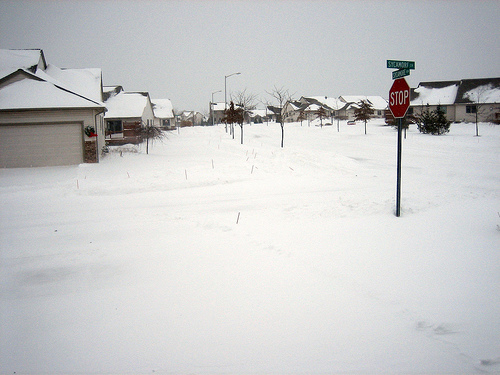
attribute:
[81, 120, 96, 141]
wreath — green, red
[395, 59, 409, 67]
street sign — green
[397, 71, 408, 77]
street sign — green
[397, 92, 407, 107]
stop sign — red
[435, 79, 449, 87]
roof — black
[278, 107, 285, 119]
tree — bare, short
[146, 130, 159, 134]
tree — bare, short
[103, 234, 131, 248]
snow — white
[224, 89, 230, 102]
pole — gray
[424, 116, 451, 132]
bush — green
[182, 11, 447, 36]
sky — gray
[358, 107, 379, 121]
tree — green